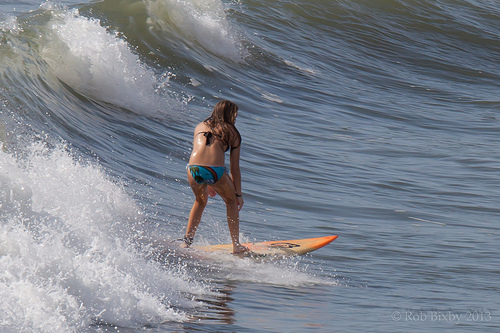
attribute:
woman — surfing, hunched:
[184, 99, 253, 257]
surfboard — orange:
[180, 234, 340, 257]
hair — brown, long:
[203, 99, 242, 152]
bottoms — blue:
[187, 164, 228, 185]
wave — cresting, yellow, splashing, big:
[2, 0, 256, 332]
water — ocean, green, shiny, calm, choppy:
[2, 1, 498, 332]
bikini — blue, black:
[189, 131, 230, 182]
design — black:
[269, 239, 300, 251]